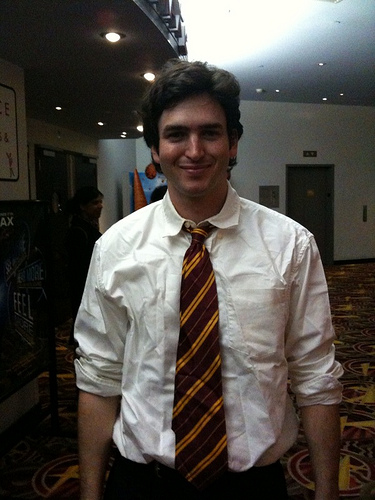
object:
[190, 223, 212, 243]
stipe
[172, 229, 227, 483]
stripe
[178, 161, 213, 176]
mouth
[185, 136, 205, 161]
nose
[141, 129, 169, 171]
ear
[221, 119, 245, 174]
ear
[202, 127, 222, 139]
eye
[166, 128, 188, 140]
eye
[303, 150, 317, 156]
sign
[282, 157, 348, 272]
door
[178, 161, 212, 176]
grin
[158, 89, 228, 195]
man's face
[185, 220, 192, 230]
button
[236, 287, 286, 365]
pocket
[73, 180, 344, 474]
shirt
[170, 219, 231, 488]
tie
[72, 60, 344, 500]
guy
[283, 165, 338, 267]
door entrance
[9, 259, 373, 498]
rug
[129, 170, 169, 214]
poster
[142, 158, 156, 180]
ball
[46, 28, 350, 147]
lights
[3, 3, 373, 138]
ceiling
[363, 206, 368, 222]
elevator panel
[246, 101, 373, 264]
wall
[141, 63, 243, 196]
head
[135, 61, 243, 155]
hair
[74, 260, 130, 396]
sleeves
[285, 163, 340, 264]
elevator door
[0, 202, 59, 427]
stand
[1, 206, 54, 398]
poster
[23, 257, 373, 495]
carpet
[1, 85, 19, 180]
sign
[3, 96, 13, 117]
e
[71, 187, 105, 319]
woman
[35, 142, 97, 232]
double doors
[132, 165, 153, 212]
cone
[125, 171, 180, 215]
advertisement